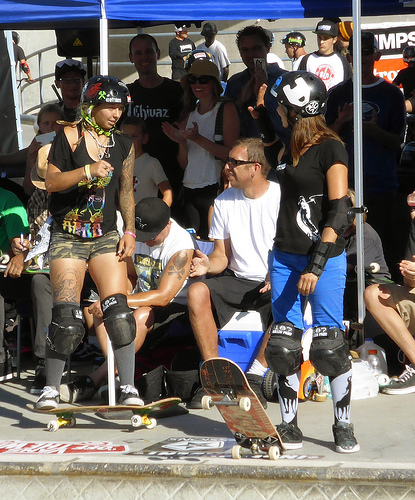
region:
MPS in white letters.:
[376, 31, 413, 50]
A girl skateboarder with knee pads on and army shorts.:
[36, 74, 145, 410]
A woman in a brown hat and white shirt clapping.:
[161, 59, 241, 232]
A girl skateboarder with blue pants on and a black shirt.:
[265, 69, 360, 453]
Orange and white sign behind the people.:
[372, 56, 411, 85]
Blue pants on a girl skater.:
[270, 242, 347, 330]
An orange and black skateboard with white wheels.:
[198, 354, 285, 460]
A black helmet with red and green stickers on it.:
[78, 74, 132, 107]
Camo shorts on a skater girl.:
[49, 229, 124, 259]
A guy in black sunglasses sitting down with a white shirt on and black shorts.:
[188, 138, 280, 409]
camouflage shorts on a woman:
[41, 224, 124, 264]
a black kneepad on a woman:
[306, 323, 353, 381]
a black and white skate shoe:
[382, 364, 413, 395]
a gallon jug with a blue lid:
[357, 336, 389, 378]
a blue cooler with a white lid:
[213, 307, 266, 378]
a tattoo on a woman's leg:
[50, 262, 85, 304]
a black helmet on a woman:
[269, 70, 331, 114]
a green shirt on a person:
[0, 188, 33, 258]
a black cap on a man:
[309, 19, 347, 42]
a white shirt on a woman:
[180, 96, 231, 192]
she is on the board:
[37, 374, 156, 417]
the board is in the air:
[198, 355, 263, 433]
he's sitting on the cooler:
[219, 277, 254, 333]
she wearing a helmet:
[92, 90, 126, 121]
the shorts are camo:
[57, 238, 74, 255]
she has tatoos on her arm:
[118, 169, 138, 199]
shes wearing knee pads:
[45, 308, 87, 355]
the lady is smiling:
[192, 85, 205, 94]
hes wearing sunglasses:
[226, 154, 244, 170]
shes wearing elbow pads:
[334, 192, 353, 236]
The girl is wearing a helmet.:
[271, 66, 327, 113]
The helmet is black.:
[273, 69, 334, 117]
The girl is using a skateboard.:
[184, 351, 312, 462]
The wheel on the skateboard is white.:
[232, 388, 255, 420]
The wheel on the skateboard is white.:
[198, 393, 219, 419]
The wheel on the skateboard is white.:
[267, 439, 284, 460]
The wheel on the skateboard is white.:
[222, 440, 243, 462]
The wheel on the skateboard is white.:
[38, 415, 62, 431]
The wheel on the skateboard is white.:
[123, 412, 151, 435]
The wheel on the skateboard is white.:
[139, 416, 159, 428]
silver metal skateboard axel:
[208, 394, 240, 410]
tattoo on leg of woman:
[50, 269, 83, 303]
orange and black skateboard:
[195, 360, 284, 473]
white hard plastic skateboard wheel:
[128, 411, 144, 429]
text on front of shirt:
[126, 98, 171, 119]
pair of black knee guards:
[259, 336, 350, 380]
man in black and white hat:
[305, 16, 344, 54]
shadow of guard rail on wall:
[29, 44, 51, 103]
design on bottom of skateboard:
[257, 431, 279, 445]